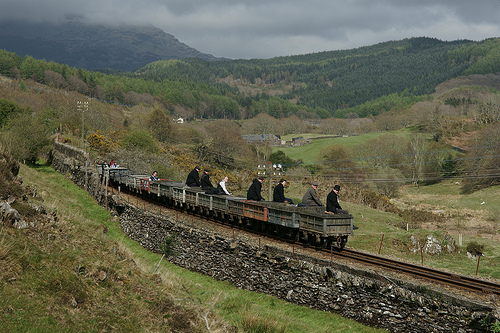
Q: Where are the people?
A: On train.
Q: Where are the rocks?
A: The hillside.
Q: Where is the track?
A: In field.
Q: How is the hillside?
A: Grassy.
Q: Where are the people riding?
A: On rails.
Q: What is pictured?
A: People sitting on carts.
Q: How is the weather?
A: Rainy.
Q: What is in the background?
A: Hills.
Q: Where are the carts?
A: On rails.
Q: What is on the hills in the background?
A: Trees.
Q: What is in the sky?
A: Clouds.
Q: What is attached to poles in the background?
A: Telephone lines.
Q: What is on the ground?
A: Grass.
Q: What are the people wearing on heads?
A: Hats.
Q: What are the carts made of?
A: Wood.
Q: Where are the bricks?
A: Under tracks.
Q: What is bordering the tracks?
A: Gravel.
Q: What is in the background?
A: Hills.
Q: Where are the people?
A: On the carts.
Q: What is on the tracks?
A: Carts.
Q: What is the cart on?
A: Tracks.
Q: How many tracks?
A: 1.